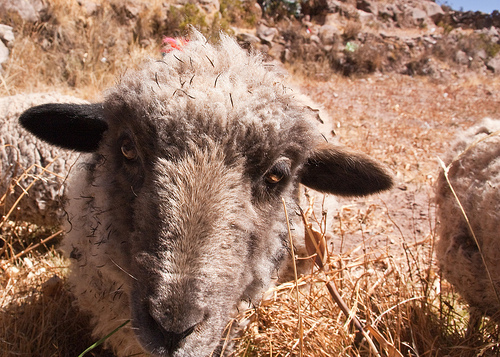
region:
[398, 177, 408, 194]
small stone on ground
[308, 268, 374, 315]
brown twigs on the ground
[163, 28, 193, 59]
pink hair on sheep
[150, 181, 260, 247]
brown wool on front of face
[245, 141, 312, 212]
sheep's gold and black eyes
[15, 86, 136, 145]
perked up black ears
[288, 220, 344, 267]
gold leaves on the branch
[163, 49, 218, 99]
single black strands on sheep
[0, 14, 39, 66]
large tan stone on ground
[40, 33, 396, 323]
large sheep in the field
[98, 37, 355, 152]
debris in the sheep's fur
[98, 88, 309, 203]
the sheep's golden eyes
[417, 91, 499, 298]
the body of a furry sheep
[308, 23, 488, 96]
grass in the background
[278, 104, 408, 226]
the sheep's extended ear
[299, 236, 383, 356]
a twig sticking up in the foreground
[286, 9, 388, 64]
debris in the background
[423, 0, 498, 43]
a small patch of blue sky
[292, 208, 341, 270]
a small brown leaf hanging on a stick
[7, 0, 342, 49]
rocks in the background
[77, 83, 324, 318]
the sheep is white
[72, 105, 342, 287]
the sheep is facing the camera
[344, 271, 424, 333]
the grass is brown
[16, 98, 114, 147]
the ear is black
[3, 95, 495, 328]
the sheep are two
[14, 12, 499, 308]
the photo was taken during the day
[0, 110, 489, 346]
the photo is an outdoor scene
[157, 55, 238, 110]
the head has black hair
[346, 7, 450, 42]
there are rocks in the background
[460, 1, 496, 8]
the sky is blue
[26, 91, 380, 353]
a sheep stares at the camera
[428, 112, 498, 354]
part of another sheep is captured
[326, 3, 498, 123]
a desert backdrop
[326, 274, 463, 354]
dry grasses show this to be an arid environment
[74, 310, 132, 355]
The only green foliage visible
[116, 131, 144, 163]
a sheep's eye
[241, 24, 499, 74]
rocks sticking out from the hillside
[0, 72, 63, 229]
another partial sheep in the shot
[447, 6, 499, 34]
trees in the distance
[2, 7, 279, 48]
shrubs and other hardy vegetation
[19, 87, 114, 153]
Sheep ears are sticking out.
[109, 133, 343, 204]
Sheep eyes are open.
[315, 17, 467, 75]
Rocks are in the background.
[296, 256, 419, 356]
The grass is brown and dry.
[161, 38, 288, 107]
The sheep has grass on top of his head.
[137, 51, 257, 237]
The wool on the sheep is ruff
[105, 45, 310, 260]
The sheep is a gray white color.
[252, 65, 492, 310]
Another sheep is sitting by the sheep.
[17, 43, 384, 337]
The sheep is sitting on the ground.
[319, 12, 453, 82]
The rocks are big.